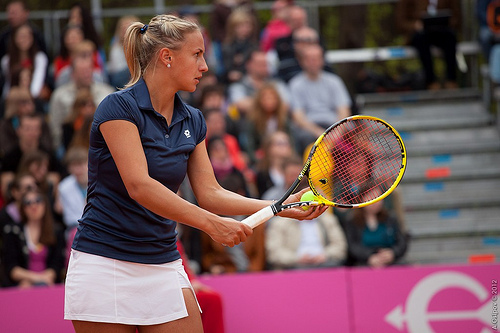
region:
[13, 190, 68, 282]
spectator in the stand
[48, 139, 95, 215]
spectator in the stand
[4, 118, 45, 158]
spectator in the stand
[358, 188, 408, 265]
spectator in the stand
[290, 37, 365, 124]
spectator in the stand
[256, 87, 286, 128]
spectator in the stand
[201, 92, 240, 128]
spectator in the stand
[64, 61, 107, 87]
spectator in the stand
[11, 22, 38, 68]
spectator in the stand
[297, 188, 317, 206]
a girl's green tennis ball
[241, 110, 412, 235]
a yellow and black racket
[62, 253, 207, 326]
a woman's white skirt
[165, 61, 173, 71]
a small earring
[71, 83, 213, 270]
a woman's blue shirt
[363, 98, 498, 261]
part of a gray stairway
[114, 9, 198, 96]
a woman's blonde hair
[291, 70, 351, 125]
a man's shirt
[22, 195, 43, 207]
a woman's sunglasses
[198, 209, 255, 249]
the hand of a woman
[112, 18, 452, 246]
a girl is holding a tennis racquet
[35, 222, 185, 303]
the woman is wearing a white skirt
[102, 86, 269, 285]
the woman is holding a blue shirt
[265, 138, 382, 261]
the woman is holding a tennis ball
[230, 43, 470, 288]
the audience is watching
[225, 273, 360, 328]
the wall is pink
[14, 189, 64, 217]
the woman is wearing sunglasses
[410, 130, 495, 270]
the steps have colors on them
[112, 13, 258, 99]
the lady is wearing a ponytail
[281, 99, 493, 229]
the racquet is yellow and black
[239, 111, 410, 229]
the tennis racket is yellow and black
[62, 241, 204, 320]
the skirt is white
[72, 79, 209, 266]
the shirt is blue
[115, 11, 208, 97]
the hair is blonde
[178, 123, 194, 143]
a white logo on the shirt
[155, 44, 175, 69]
an earring in the ear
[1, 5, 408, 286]
people are sitting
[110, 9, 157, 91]
the hair is in a ponytail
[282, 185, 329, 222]
the ball is in her hand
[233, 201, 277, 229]
the tennis racket handle is white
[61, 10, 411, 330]
Woman holding a tennis racket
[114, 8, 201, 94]
Blonde hair in a ponytail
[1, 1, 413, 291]
Spectators watching the game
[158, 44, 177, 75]
A white earring on an ear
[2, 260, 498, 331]
A pink wall with white writing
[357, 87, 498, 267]
A set of stairs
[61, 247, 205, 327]
A white tennis racket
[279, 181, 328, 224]
A tennis ball in a hand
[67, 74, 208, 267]
A navy blue shirt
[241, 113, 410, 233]
Yellow and black tennis racket with a white handle